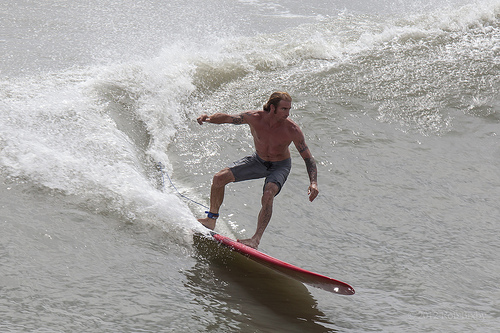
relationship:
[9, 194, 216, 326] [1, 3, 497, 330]
ripples in water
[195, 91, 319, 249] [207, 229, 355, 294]
man on surfboard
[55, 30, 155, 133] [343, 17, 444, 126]
water has wave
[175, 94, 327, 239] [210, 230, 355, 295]
man on board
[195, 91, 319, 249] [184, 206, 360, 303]
man on board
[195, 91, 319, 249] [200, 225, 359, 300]
man on board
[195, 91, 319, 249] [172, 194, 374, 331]
man on board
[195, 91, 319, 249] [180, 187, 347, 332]
man on surfboard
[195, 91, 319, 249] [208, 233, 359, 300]
man on surfboard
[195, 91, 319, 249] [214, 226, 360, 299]
man on surfboard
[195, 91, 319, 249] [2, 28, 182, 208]
man riding wave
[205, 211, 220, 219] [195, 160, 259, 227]
band around leg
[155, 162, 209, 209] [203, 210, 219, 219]
blue cord attached to band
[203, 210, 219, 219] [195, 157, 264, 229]
band on man's leg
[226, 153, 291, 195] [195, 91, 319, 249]
shorts on man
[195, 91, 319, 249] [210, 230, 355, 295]
man on board